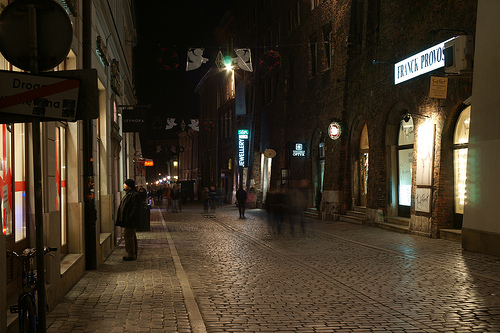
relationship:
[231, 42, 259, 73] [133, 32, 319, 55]
banner hanging on line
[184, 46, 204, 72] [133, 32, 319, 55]
banner hanging on line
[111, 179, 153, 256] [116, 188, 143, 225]
man wearing jacket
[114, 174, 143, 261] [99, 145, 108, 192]
person looking into window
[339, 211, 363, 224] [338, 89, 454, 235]
step in front of doorway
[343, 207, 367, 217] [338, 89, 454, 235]
step in front of doorway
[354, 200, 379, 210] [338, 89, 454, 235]
step in front of doorway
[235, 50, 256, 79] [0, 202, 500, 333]
decorations above street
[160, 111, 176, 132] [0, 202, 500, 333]
decorations above street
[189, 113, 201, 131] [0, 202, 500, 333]
decorations above street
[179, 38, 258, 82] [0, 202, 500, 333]
decorations above street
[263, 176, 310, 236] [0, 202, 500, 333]
people walking on street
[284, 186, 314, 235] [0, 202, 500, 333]
people walking on street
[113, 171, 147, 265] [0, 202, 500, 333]
people walking on street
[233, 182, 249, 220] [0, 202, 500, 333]
people walking on street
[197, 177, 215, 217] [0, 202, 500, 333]
people walking on street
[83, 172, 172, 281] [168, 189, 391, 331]
person on street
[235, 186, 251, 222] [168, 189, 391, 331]
person on street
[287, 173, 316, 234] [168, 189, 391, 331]
person on street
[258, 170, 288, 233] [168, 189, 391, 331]
person on street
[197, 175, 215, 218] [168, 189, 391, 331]
person on street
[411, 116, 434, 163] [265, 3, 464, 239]
light on building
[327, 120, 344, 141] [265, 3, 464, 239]
light on building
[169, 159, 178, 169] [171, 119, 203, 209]
light on building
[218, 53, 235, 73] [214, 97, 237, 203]
light on building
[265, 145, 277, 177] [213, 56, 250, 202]
light on building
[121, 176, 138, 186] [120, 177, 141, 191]
hat on head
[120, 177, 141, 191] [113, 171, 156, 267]
head on person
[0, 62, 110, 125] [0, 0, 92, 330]
sign on building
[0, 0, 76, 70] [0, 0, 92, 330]
sign on building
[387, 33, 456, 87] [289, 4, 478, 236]
sign on building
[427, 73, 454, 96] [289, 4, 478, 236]
sign on building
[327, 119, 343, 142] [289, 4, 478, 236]
sign on building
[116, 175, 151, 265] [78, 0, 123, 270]
person looking at store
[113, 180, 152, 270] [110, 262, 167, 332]
person on sidewalk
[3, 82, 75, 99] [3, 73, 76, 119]
line on sign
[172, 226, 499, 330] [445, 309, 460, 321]
floor made of pebbles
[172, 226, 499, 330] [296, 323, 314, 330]
floor made of pebbles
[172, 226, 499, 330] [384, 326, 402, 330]
floor made of pebbles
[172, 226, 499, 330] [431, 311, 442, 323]
floor made of pebbles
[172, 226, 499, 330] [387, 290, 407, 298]
floor made of pebbles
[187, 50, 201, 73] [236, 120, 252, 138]
angel by signs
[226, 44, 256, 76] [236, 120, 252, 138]
angel by signs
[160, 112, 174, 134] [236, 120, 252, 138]
angel by signs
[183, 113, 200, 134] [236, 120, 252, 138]
angel by signs